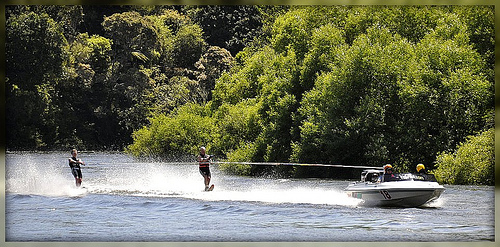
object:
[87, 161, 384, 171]
rope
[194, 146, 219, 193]
people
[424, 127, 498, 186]
tree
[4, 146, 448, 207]
water mist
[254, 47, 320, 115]
leaves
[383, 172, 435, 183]
windshield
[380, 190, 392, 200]
number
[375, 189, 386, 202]
number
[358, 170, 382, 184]
motor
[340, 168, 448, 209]
boat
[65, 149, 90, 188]
guy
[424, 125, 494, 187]
plants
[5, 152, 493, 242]
wake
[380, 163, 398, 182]
people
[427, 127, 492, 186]
tree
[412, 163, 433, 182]
person